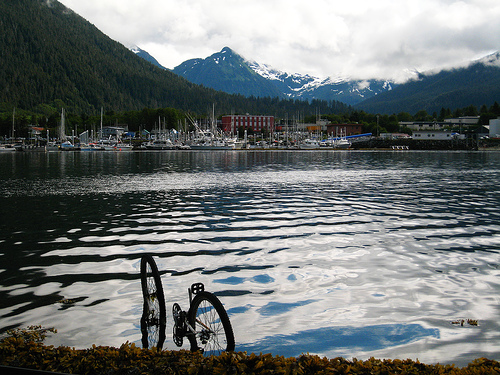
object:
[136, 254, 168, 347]
tire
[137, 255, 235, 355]
bicycle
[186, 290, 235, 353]
wheel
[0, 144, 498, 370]
water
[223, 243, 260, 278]
ripples